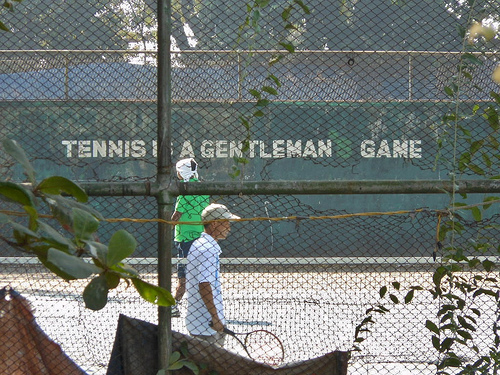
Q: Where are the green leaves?
A: In front of the fence.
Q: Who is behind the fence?
A: Tennis players.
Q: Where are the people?
A: On tennis court.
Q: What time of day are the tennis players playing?
A: Daylight time.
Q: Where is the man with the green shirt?
A: Behind the net.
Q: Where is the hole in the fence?
A: Near the metal frame.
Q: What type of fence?
A: Chain link.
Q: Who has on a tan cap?
A: Man in white shirt.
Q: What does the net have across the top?
A: White fabric.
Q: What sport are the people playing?
A: Tennis.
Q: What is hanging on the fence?
A: A tarp.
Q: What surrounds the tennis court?
A: A fence.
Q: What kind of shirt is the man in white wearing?
A: A polo shirt.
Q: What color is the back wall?
A: Green.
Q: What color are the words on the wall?
A: White.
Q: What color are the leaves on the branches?
A: Green.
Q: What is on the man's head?
A: A baseball cap.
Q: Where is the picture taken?
A: A tennis court.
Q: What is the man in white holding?
A: A racket.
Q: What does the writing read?
A: Tennis is a gentleman's game.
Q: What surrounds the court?
A: A fence.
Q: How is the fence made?
A: Of metal.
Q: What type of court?
A: Tennis.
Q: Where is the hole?
A: In court.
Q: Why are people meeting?
A: For tennis.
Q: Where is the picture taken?
A: Tennis court.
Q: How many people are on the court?
A: Two.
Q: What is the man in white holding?
A: Racket.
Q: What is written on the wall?
A: Tennis is a gentleman's game.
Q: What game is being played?
A: Tennis.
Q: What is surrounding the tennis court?
A: A fence.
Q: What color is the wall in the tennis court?
A: Green.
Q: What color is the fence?
A: Gray.